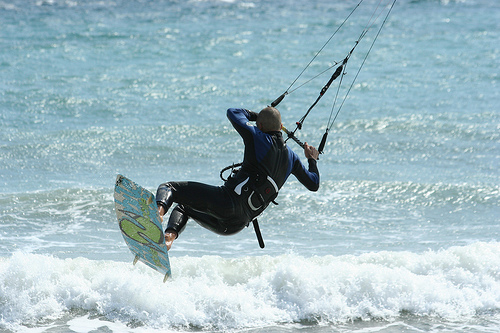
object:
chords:
[271, 0, 363, 107]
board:
[113, 173, 177, 284]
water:
[361, 170, 500, 222]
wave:
[288, 245, 488, 322]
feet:
[155, 203, 167, 225]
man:
[153, 104, 322, 251]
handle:
[279, 127, 313, 156]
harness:
[224, 137, 290, 218]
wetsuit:
[155, 108, 320, 233]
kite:
[351, 0, 475, 27]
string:
[316, 2, 398, 153]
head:
[254, 106, 283, 134]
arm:
[287, 155, 322, 192]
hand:
[304, 142, 321, 161]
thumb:
[305, 144, 310, 150]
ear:
[255, 122, 262, 130]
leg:
[153, 180, 219, 221]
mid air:
[77, 98, 349, 314]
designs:
[117, 209, 162, 255]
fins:
[162, 270, 170, 282]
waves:
[188, 256, 280, 332]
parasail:
[260, 0, 399, 160]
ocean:
[0, 0, 500, 333]